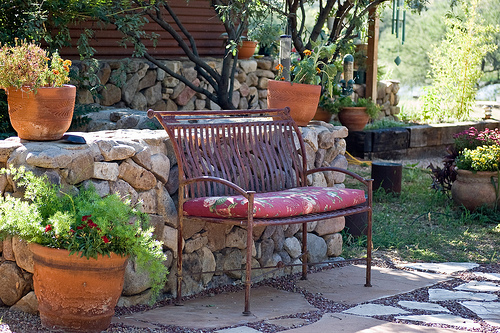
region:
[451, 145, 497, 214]
a stoneware planter with a green plant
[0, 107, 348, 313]
two intersecting low stone walls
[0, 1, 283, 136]
stone wall topped by wood panel wall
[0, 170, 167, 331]
planter in front of wall with a trailing feathery green plant in it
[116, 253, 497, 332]
ground paved with large flat stones and small stones as mortar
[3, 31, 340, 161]
two planters with greenery in them on top of stone wall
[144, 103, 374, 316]
rusted metal bench in front of stone wall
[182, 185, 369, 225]
red flowered cushion on bench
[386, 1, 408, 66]
a hanging wind chime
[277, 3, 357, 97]
hanging tube-shaped feeders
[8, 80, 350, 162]
two flower pots on a rock wall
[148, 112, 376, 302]
a bench with a cushion on it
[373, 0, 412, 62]
green wind chimes next to the tree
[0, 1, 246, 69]
paneling of a home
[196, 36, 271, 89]
a flower pot on a rock wall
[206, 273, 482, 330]
gravel between stones on the ground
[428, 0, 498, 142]
a tree next to a wooden ledge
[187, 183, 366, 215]
a floral cushion with a red background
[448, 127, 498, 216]
pink and yellow flowers in a flower pot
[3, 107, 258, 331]
a flower pot to the left of the bench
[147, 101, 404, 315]
bench by the flowers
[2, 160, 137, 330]
pot by the bench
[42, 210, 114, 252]
red flowers in the pot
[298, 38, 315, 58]
yellow flower in the pot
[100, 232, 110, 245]
red flower in the pot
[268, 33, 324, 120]
pot with yellow flowers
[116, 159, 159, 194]
stone by the bench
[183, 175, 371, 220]
cushion on the bench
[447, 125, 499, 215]
purple flowers by the pot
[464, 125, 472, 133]
purple flower by the pot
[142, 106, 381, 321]
a bench next to the wall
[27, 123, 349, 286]
a stone wall behind the bench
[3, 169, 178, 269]
some flowering plants in a pot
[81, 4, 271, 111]
a tree with some green leaves on it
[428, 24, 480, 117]
a short tree with light green leaves on it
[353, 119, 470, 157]
a short wooden fence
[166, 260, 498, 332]
a walkway made of stone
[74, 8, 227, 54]
part of a wall behind the fence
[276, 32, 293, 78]
a little birdfeeder standing by the plant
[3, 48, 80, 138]
some plants in a pot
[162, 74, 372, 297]
red bench sitting by the rock wall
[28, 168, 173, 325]
clay planter on a porch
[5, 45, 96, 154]
clay planter on a porch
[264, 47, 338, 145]
clay planter on a porch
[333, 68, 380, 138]
clay planter on a ledge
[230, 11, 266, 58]
clay planter on a rock wall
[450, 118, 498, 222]
clay planter on the grass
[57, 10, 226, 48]
brown siding on the house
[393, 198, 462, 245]
grass in the yard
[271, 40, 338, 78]
flowers in the planter